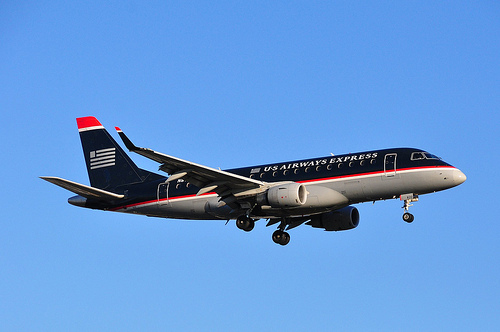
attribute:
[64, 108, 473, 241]
plane — blue gray, red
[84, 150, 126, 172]
symbol — flag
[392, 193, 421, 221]
wheel — black, round, down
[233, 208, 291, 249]
hind wheel — lowered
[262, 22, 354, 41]
sky — blue, distant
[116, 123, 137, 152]
wing tip — raised, red